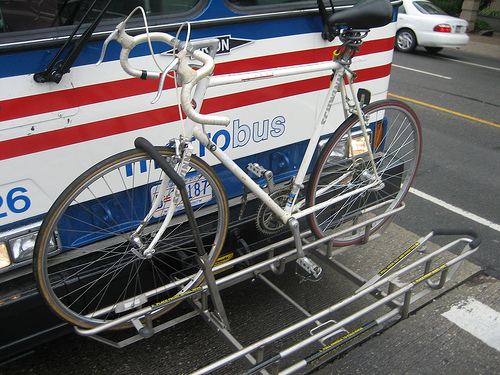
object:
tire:
[305, 93, 425, 248]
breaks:
[95, 24, 186, 115]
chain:
[321, 29, 379, 62]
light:
[347, 127, 375, 158]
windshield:
[2, 2, 305, 40]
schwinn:
[319, 72, 345, 126]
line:
[423, 93, 498, 126]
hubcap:
[398, 32, 412, 50]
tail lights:
[430, 21, 451, 34]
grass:
[473, 18, 490, 32]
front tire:
[29, 141, 236, 337]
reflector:
[109, 293, 152, 316]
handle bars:
[90, 19, 239, 127]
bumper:
[3, 283, 51, 357]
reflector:
[372, 122, 391, 153]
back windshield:
[412, 1, 450, 17]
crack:
[423, 157, 454, 183]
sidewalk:
[471, 35, 493, 57]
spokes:
[387, 133, 412, 170]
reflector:
[356, 86, 378, 105]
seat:
[320, 1, 399, 33]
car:
[396, 1, 479, 59]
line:
[393, 60, 463, 89]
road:
[435, 130, 492, 181]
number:
[1, 185, 40, 215]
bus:
[3, 2, 413, 280]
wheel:
[53, 131, 217, 310]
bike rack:
[118, 234, 469, 374]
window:
[6, 4, 187, 24]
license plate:
[131, 176, 205, 207]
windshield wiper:
[37, 12, 106, 88]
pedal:
[294, 252, 331, 279]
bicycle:
[39, 54, 415, 290]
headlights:
[2, 231, 53, 265]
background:
[395, 4, 496, 271]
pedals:
[287, 252, 324, 280]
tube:
[220, 144, 292, 203]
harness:
[139, 133, 231, 321]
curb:
[462, 35, 499, 54]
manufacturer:
[159, 31, 244, 72]